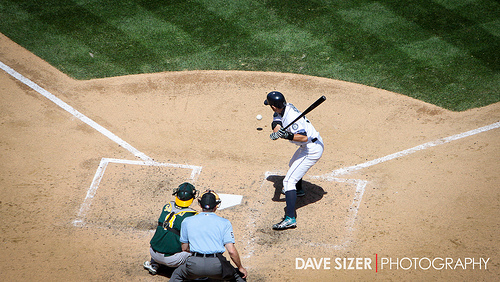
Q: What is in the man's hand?
A: Bat.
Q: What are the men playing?
A: Baseball.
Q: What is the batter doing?
A: Swinging bat.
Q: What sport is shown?
A: Baseball.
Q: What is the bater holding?
A: Baseball bat.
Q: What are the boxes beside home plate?
A: Batter boxes.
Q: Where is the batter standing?
A: Right batter box.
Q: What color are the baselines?
A: White.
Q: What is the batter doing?
A: Swinging.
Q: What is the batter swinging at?
A: Baseball.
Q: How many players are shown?
A: Two.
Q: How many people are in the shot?
A: Three.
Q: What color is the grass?
A: Green.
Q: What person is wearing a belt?
A: Umpire.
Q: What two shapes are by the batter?
A: Squares.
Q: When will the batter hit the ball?
A: Right now.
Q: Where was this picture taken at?
A: Baseball field.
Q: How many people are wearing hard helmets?
A: 1.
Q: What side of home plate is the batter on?
A: Right.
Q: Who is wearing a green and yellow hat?
A: Catcher.